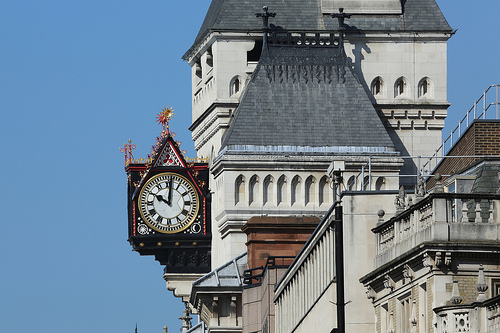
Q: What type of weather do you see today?
A: It is clear.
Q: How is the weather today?
A: It is clear.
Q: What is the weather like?
A: It is clear.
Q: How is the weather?
A: It is clear.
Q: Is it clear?
A: Yes, it is clear.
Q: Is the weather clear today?
A: Yes, it is clear.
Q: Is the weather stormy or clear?
A: It is clear.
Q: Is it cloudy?
A: No, it is clear.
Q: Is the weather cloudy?
A: No, it is clear.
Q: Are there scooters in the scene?
A: No, there are no scooters.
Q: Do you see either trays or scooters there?
A: No, there are no scooters or trays.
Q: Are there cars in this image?
A: No, there are no cars.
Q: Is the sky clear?
A: Yes, the sky is clear.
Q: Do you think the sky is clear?
A: Yes, the sky is clear.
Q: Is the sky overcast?
A: No, the sky is clear.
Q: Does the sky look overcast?
A: No, the sky is clear.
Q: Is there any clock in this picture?
A: Yes, there is a clock.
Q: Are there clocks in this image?
A: Yes, there is a clock.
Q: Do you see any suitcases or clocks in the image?
A: Yes, there is a clock.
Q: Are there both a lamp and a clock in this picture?
A: No, there is a clock but no lamps.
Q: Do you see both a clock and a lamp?
A: No, there is a clock but no lamps.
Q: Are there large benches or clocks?
A: Yes, there is a large clock.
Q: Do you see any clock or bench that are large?
A: Yes, the clock is large.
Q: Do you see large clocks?
A: Yes, there is a large clock.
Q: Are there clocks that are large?
A: Yes, there is a clock that is large.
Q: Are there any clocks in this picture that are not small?
A: Yes, there is a large clock.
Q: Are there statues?
A: No, there are no statues.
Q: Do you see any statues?
A: No, there are no statues.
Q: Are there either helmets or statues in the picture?
A: No, there are no statues or helmets.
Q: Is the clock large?
A: Yes, the clock is large.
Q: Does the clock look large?
A: Yes, the clock is large.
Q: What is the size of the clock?
A: The clock is large.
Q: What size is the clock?
A: The clock is large.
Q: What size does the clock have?
A: The clock has large size.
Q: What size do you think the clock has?
A: The clock has large size.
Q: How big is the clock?
A: The clock is large.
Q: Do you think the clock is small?
A: No, the clock is large.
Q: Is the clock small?
A: No, the clock is large.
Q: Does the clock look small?
A: No, the clock is large.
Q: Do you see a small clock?
A: No, there is a clock but it is large.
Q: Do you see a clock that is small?
A: No, there is a clock but it is large.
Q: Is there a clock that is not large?
A: No, there is a clock but it is large.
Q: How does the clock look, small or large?
A: The clock is large.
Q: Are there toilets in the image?
A: No, there are no toilets.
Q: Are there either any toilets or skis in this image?
A: No, there are no toilets or skis.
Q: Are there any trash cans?
A: No, there are no trash cans.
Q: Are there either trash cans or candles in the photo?
A: No, there are no trash cans or candles.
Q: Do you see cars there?
A: No, there are no cars.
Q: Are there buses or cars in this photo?
A: No, there are no cars or buses.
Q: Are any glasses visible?
A: No, there are no glasses.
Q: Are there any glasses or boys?
A: No, there are no glasses or boys.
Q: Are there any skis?
A: No, there are no skis.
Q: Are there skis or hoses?
A: No, there are no skis or hoses.